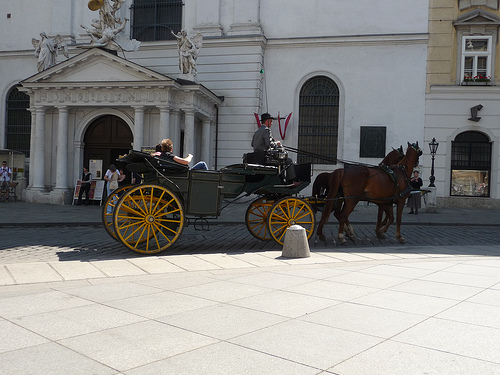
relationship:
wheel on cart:
[115, 151, 195, 255] [115, 154, 344, 229]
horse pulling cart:
[318, 136, 424, 243] [115, 154, 344, 229]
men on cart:
[142, 130, 203, 185] [115, 154, 344, 229]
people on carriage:
[139, 130, 205, 175] [120, 153, 343, 227]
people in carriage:
[139, 130, 205, 175] [120, 153, 343, 227]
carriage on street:
[120, 153, 343, 227] [25, 242, 366, 368]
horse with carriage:
[318, 136, 424, 243] [120, 153, 343, 227]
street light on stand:
[419, 132, 451, 197] [428, 161, 450, 203]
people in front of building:
[69, 156, 95, 202] [40, 48, 218, 223]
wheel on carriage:
[115, 151, 195, 255] [120, 153, 343, 227]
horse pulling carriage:
[318, 136, 424, 243] [120, 153, 343, 227]